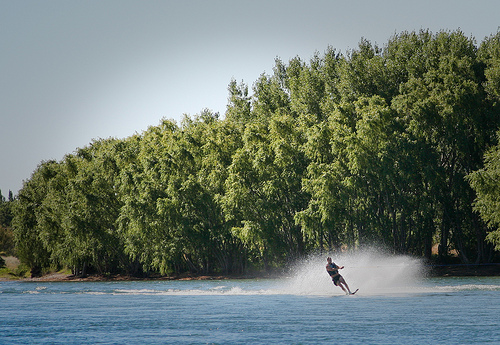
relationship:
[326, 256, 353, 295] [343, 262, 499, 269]
man holding on to cable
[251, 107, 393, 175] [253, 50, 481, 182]
leaves on trees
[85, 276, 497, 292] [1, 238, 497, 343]
waves on water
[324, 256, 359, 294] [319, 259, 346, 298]
skating wearing shorts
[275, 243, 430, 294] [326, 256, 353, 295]
water spray from man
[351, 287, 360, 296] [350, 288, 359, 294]
front of ski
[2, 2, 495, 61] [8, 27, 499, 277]
sky above trees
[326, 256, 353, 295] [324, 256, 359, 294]
man on skating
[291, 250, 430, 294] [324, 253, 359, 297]
water splashing behind skiier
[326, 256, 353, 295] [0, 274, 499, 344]
man splashing water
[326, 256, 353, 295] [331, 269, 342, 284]
man wearing shorts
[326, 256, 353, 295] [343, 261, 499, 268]
man holding cable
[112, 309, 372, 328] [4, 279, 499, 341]
ripple in water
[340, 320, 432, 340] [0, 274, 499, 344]
ripple in water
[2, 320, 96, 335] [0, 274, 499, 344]
ripple in water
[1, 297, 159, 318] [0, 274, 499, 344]
ripple in water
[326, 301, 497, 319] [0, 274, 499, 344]
ripple in water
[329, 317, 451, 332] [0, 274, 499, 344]
ripple in water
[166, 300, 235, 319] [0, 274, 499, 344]
ripple in water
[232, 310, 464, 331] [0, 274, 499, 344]
ripple in water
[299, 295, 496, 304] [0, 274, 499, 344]
ripple in water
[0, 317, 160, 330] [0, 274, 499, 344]
ripple in water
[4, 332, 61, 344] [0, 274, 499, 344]
ripple in water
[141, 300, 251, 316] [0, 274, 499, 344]
ripple in water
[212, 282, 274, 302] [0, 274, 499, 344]
ripple in water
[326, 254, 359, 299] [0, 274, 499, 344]
man skating in water